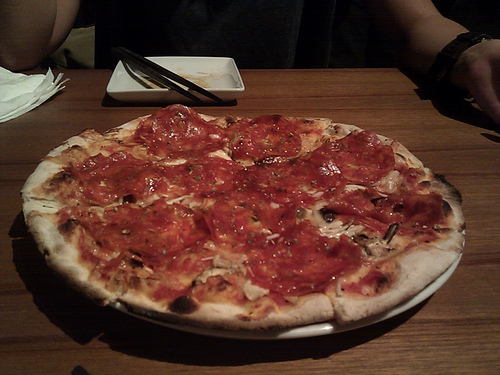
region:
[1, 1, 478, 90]
a person sitting at the table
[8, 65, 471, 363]
a wooden table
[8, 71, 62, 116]
a paper towel on the table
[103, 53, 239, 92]
a white bowl on the table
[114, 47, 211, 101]
chop sticks on the bowl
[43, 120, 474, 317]
a pizza on the plate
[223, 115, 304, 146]
pepperoni on the pizza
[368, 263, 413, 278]
the crust on the pizza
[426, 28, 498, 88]
a watch on the person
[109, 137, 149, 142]
cheese on the pizza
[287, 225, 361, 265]
topping on the pizza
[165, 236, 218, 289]
topping on the pizza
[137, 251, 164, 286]
topping on the pizza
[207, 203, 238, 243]
topping on the pizza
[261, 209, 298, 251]
topping on the pizza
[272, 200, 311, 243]
topping on the pizza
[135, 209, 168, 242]
topping on the pizza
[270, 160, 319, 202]
topping on the pizza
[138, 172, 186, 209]
topping on the pizza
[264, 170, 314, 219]
topping on the pizza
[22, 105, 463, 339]
Baked pepperoni pizza on plate.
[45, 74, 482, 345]
A pizza on the table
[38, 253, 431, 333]
The crust of the pizza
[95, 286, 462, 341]
The plate is the color white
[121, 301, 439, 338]
The plate is round in shape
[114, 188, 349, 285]
The pepperoni on the pizza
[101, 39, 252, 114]
A tiny plate on the table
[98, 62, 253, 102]
The tiny plate is the color white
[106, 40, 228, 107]
The chop sticks on the plate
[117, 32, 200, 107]
The chop sticks are black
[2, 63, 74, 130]
The napkin on the table is white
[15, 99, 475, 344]
A medium sized pepperoni pizza on a white plate.